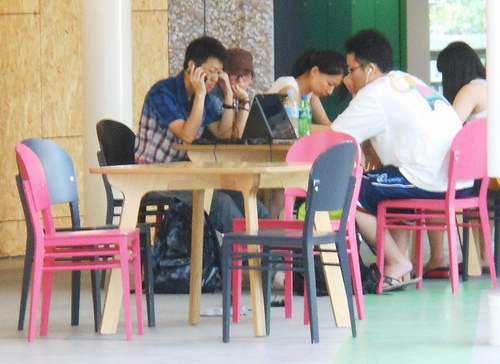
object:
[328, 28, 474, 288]
person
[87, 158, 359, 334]
table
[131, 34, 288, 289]
person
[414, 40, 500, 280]
person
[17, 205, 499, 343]
legs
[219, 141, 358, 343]
chair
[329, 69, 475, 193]
shirt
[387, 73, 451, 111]
design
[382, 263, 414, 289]
foot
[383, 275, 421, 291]
flip flop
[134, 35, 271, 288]
man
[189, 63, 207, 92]
hand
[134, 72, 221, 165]
shirt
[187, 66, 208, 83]
phone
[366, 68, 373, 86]
earbuds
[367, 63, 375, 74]
ear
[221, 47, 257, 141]
girl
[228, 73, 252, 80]
glasses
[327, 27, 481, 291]
man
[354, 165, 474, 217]
shorts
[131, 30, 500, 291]
people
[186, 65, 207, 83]
cell phone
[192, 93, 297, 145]
laptop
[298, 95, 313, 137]
bottle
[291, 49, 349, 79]
hair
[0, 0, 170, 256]
wall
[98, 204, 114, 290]
leg